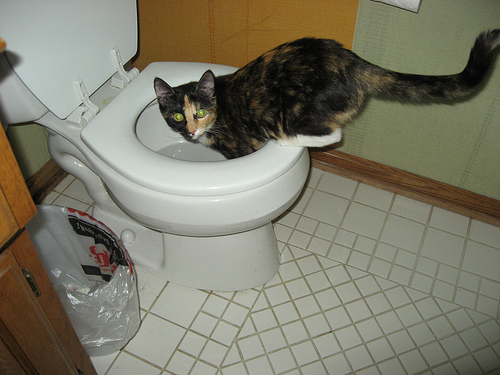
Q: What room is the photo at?
A: It is at the bathroom.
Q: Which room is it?
A: It is a bathroom.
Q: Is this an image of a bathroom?
A: Yes, it is showing a bathroom.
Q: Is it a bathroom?
A: Yes, it is a bathroom.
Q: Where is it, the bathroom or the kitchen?
A: It is the bathroom.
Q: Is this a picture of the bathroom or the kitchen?
A: It is showing the bathroom.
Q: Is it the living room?
A: No, it is the bathroom.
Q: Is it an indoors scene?
A: Yes, it is indoors.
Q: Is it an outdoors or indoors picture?
A: It is indoors.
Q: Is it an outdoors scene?
A: No, it is indoors.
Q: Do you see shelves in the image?
A: No, there are no shelves.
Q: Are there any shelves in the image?
A: No, there are no shelves.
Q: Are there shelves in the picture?
A: No, there are no shelves.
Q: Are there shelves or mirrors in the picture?
A: No, there are no shelves or mirrors.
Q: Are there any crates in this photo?
A: No, there are no crates.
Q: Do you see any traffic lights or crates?
A: No, there are no crates or traffic lights.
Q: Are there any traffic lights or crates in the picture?
A: No, there are no crates or traffic lights.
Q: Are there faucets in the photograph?
A: No, there are no faucets.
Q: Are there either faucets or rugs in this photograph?
A: No, there are no faucets or rugs.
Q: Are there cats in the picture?
A: Yes, there is a cat.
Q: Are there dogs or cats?
A: Yes, there is a cat.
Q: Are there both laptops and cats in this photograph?
A: No, there is a cat but no laptops.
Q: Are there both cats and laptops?
A: No, there is a cat but no laptops.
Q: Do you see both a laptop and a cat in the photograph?
A: No, there is a cat but no laptops.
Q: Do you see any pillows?
A: No, there are no pillows.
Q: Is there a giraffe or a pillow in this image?
A: No, there are no pillows or giraffes.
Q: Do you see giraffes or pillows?
A: No, there are no pillows or giraffes.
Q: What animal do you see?
A: The animal is a cat.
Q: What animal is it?
A: The animal is a cat.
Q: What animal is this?
A: This is a cat.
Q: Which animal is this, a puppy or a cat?
A: This is a cat.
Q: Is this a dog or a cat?
A: This is a cat.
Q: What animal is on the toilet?
A: The cat is on the toilet.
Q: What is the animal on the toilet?
A: The animal is a cat.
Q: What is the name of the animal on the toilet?
A: The animal is a cat.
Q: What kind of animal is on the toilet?
A: The animal is a cat.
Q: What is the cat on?
A: The cat is on the toilet.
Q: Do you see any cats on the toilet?
A: Yes, there is a cat on the toilet.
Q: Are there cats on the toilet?
A: Yes, there is a cat on the toilet.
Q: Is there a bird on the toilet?
A: No, there is a cat on the toilet.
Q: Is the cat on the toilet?
A: Yes, the cat is on the toilet.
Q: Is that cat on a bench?
A: No, the cat is on the toilet.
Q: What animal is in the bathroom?
A: The cat is in the bathroom.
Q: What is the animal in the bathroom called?
A: The animal is a cat.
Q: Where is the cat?
A: The cat is in the bathroom.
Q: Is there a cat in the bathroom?
A: Yes, there is a cat in the bathroom.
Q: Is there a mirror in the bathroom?
A: No, there is a cat in the bathroom.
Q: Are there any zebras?
A: No, there are no zebras.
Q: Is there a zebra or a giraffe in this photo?
A: No, there are no zebras or giraffes.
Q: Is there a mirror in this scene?
A: No, there are no mirrors.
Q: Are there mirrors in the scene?
A: No, there are no mirrors.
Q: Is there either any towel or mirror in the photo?
A: No, there are no mirrors or towels.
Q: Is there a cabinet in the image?
A: Yes, there is a cabinet.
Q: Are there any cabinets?
A: Yes, there is a cabinet.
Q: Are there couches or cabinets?
A: Yes, there is a cabinet.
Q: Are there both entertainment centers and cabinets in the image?
A: No, there is a cabinet but no entertainment centers.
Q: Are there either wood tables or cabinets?
A: Yes, there is a wood cabinet.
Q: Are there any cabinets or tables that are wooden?
A: Yes, the cabinet is wooden.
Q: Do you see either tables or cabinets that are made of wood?
A: Yes, the cabinet is made of wood.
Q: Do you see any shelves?
A: No, there are no shelves.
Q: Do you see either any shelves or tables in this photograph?
A: No, there are no shelves or tables.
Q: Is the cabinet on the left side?
A: Yes, the cabinet is on the left of the image.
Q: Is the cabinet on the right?
A: No, the cabinet is on the left of the image.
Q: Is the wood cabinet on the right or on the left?
A: The cabinet is on the left of the image.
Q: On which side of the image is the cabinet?
A: The cabinet is on the left of the image.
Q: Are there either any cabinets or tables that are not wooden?
A: No, there is a cabinet but it is wooden.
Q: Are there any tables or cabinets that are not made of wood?
A: No, there is a cabinet but it is made of wood.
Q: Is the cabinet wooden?
A: Yes, the cabinet is wooden.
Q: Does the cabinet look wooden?
A: Yes, the cabinet is wooden.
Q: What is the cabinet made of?
A: The cabinet is made of wood.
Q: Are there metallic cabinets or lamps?
A: No, there is a cabinet but it is wooden.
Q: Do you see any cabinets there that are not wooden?
A: No, there is a cabinet but it is wooden.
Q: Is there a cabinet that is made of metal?
A: No, there is a cabinet but it is made of wood.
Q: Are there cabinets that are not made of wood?
A: No, there is a cabinet but it is made of wood.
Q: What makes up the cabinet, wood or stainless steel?
A: The cabinet is made of wood.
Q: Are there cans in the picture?
A: Yes, there is a can.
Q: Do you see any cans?
A: Yes, there is a can.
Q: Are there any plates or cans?
A: Yes, there is a can.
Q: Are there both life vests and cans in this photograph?
A: No, there is a can but no life jackets.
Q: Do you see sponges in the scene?
A: No, there are no sponges.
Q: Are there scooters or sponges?
A: No, there are no sponges or scooters.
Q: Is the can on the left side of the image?
A: Yes, the can is on the left of the image.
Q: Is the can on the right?
A: No, the can is on the left of the image.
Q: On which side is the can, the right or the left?
A: The can is on the left of the image.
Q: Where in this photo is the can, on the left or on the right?
A: The can is on the left of the image.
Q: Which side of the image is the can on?
A: The can is on the left of the image.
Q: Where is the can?
A: The can is on the floor.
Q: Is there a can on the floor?
A: Yes, there is a can on the floor.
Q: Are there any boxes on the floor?
A: No, there is a can on the floor.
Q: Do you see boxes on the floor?
A: No, there is a can on the floor.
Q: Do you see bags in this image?
A: Yes, there is a bag.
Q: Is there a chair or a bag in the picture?
A: Yes, there is a bag.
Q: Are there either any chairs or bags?
A: Yes, there is a bag.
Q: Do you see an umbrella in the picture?
A: No, there are no umbrellas.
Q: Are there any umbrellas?
A: No, there are no umbrellas.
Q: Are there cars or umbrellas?
A: No, there are no umbrellas or cars.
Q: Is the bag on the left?
A: Yes, the bag is on the left of the image.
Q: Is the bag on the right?
A: No, the bag is on the left of the image.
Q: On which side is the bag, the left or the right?
A: The bag is on the left of the image.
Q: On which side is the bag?
A: The bag is on the left of the image.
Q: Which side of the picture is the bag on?
A: The bag is on the left of the image.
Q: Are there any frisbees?
A: No, there are no frisbees.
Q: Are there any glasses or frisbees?
A: No, there are no frisbees or glasses.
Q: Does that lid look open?
A: Yes, the lid is open.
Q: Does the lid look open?
A: Yes, the lid is open.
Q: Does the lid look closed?
A: No, the lid is open.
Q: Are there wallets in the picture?
A: No, there are no wallets.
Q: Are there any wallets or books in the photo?
A: No, there are no wallets or books.